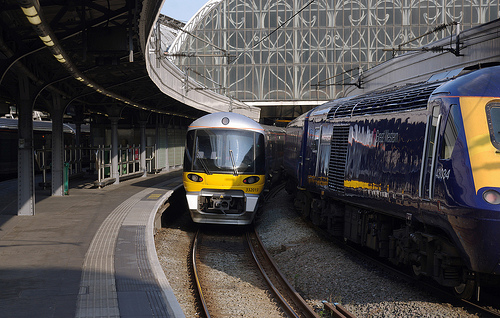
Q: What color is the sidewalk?
A: Grey.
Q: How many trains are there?
A: Two.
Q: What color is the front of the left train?
A: Yellow.